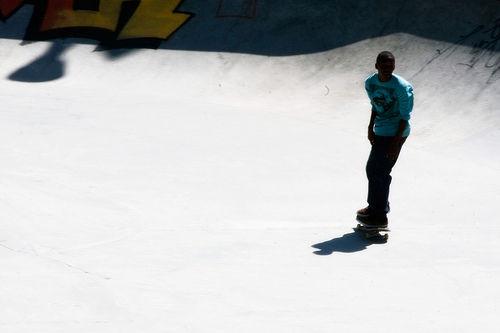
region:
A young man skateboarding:
[305, 47, 417, 259]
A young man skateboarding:
[305, 42, 415, 257]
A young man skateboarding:
[306, 41, 419, 261]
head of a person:
[374, 43, 399, 78]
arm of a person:
[388, 98, 413, 140]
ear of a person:
[373, 60, 378, 68]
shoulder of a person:
[358, 71, 417, 94]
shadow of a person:
[318, 225, 357, 260]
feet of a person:
[353, 205, 397, 227]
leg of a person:
[355, 146, 397, 202]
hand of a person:
[368, 128, 378, 143]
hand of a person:
[379, 135, 403, 157]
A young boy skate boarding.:
[357, 48, 399, 243]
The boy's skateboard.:
[348, 218, 394, 244]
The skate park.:
[22, 48, 307, 325]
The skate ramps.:
[250, 18, 496, 58]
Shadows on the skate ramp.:
[9, 27, 131, 105]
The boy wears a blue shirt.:
[365, 73, 413, 138]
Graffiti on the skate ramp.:
[38, 2, 197, 47]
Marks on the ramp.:
[412, 35, 499, 87]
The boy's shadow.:
[304, 233, 374, 256]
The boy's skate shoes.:
[357, 206, 390, 225]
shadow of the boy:
[306, 217, 403, 274]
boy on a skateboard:
[334, 42, 439, 249]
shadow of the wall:
[1, 6, 478, 55]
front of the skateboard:
[361, 220, 396, 252]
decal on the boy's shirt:
[363, 87, 397, 120]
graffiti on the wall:
[22, 8, 187, 50]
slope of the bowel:
[1, 3, 496, 139]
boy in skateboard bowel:
[0, 27, 480, 298]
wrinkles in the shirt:
[395, 85, 419, 120]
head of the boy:
[363, 48, 408, 78]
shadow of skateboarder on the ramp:
[315, 227, 382, 267]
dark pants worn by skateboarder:
[362, 137, 397, 231]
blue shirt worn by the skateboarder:
[365, 69, 414, 134]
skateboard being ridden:
[357, 215, 391, 242]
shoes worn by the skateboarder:
[357, 208, 392, 221]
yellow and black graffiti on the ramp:
[2, 2, 191, 49]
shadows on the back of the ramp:
[5, 5, 490, 77]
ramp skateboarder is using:
[3, 3, 489, 329]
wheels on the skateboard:
[355, 225, 390, 250]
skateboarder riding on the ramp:
[354, 52, 414, 239]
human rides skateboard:
[352, 50, 414, 246]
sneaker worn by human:
[362, 214, 389, 231]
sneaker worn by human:
[357, 202, 388, 219]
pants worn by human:
[365, 134, 404, 217]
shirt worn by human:
[362, 70, 416, 140]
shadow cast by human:
[310, 221, 395, 259]